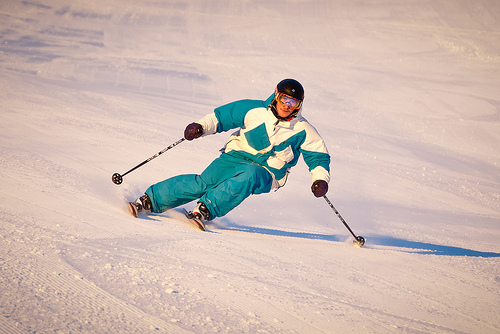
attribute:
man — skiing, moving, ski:
[129, 78, 332, 234]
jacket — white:
[193, 90, 331, 192]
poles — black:
[114, 134, 189, 184]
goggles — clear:
[276, 90, 300, 110]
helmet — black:
[275, 76, 305, 102]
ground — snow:
[2, 4, 500, 332]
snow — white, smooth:
[3, 3, 494, 242]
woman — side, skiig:
[127, 77, 329, 232]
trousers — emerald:
[148, 152, 273, 227]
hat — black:
[275, 76, 304, 103]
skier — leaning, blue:
[127, 78, 332, 234]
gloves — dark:
[185, 122, 203, 142]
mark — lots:
[125, 55, 209, 81]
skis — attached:
[125, 197, 206, 231]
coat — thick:
[197, 92, 333, 190]